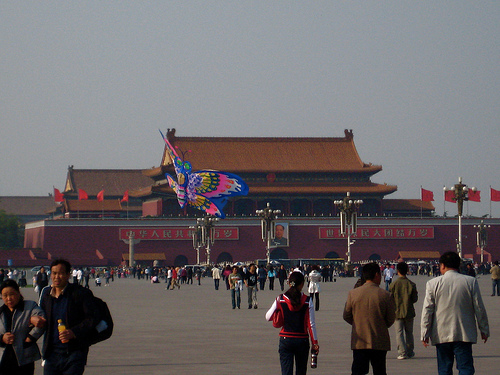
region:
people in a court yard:
[3, 242, 497, 374]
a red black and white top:
[264, 288, 326, 341]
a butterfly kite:
[158, 120, 255, 215]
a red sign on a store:
[121, 230, 241, 240]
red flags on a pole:
[415, 186, 495, 216]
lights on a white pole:
[441, 177, 476, 244]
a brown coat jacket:
[347, 282, 394, 350]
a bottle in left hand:
[52, 317, 76, 347]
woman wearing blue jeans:
[281, 346, 289, 361]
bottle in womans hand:
[306, 346, 321, 368]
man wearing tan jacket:
[361, 302, 380, 331]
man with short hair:
[364, 266, 376, 277]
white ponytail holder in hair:
[284, 278, 299, 290]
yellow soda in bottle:
[52, 316, 69, 334]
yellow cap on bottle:
[53, 316, 65, 323]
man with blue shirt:
[56, 298, 63, 310]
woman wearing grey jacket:
[18, 313, 28, 325]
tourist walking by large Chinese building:
[44, 260, 121, 373]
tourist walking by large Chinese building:
[340, 248, 382, 373]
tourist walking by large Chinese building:
[388, 260, 420, 361]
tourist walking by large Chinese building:
[430, 244, 482, 374]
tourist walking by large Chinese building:
[225, 258, 239, 313]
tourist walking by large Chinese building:
[245, 259, 259, 306]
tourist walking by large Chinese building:
[170, 264, 178, 290]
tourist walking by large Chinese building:
[210, 261, 220, 298]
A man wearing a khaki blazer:
[421, 250, 490, 373]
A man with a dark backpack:
[36, 258, 113, 373]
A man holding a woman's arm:
[0, 258, 113, 373]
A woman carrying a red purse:
[266, 270, 319, 373]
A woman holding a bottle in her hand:
[266, 271, 319, 373]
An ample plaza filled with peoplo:
[0, 260, 498, 373]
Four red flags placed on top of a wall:
[420, 184, 499, 217]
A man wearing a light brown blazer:
[343, 262, 396, 374]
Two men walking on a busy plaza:
[343, 250, 488, 374]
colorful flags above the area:
[163, 130, 248, 220]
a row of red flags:
[418, 188, 498, 219]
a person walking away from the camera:
[266, 267, 318, 372]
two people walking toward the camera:
[0, 263, 111, 374]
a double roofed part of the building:
[132, 129, 397, 214]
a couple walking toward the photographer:
[225, 262, 260, 312]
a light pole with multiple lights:
[332, 190, 364, 263]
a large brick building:
[22, 220, 498, 272]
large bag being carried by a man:
[60, 283, 114, 350]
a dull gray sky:
[1, 0, 498, 219]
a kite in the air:
[142, 152, 334, 306]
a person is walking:
[256, 255, 326, 372]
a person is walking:
[352, 252, 392, 352]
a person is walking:
[43, 263, 102, 353]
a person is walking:
[420, 257, 480, 369]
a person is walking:
[390, 262, 420, 348]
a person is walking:
[304, 263, 326, 314]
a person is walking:
[225, 267, 238, 310]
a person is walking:
[167, 259, 186, 294]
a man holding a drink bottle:
[54, 314, 73, 346]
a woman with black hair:
[282, 268, 311, 306]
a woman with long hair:
[284, 267, 306, 312]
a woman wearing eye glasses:
[1, 287, 16, 301]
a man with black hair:
[437, 248, 459, 270]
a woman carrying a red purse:
[265, 287, 290, 329]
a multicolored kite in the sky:
[159, 127, 242, 232]